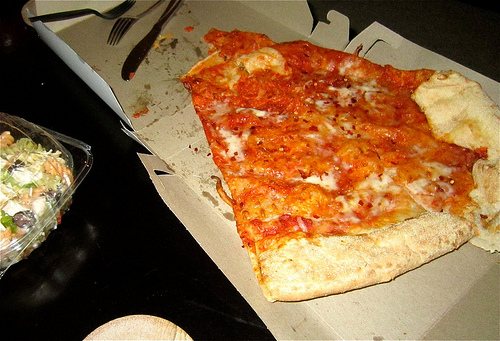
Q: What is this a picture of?
A: Pizza.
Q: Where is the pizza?
A: In the box.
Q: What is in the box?
A: Pizza.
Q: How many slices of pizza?
A: One.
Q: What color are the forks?
A: Black.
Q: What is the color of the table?
A: Black.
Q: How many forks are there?
A: Two.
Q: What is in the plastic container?
A: Salad.